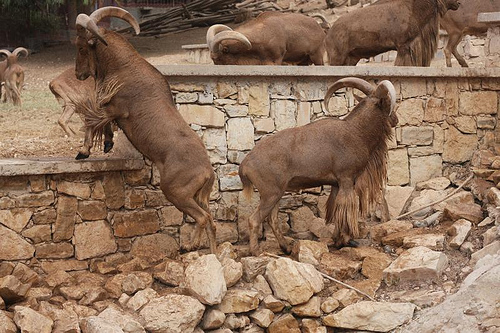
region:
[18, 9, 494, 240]
numerous rams in enclousure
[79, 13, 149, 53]
rams have brown horns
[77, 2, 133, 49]
brown horns are curved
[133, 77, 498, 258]
stone wall in enclosure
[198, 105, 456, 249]
stone wall is light brown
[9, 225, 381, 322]
stones piled on ground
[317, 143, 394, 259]
rams have long drooping manes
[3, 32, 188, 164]
brown dirt behind wall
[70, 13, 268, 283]
ram is climbing wall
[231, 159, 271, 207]
ram has short brown tail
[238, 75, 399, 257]
the animal on the rocks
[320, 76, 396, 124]
the horns on the animal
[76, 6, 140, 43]
the horns on the animal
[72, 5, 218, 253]
the animal climbing on the rock wall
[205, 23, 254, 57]
the horns on the animal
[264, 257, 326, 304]
the large rock on the ground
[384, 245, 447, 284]
the large rock on the ground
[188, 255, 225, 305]
the large rock on the ground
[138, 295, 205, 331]
the large rock on the ground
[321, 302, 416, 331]
the large rock on the ground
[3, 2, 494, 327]
Goats in a rocky surroundings.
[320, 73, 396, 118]
Goat with long horns.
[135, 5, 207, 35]
Background with stacked stones panels.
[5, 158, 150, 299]
Stone fenced wall.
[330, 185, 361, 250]
Goat's front leg is covered with long hair.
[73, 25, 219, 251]
Goat's fur is brown.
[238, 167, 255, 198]
Goat has short tail.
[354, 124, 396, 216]
Long hair hanging on the goat's chest.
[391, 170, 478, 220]
Long stick of wood among the stones.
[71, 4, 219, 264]
Goat climbing up the fence.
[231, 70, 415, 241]
brown mountain cow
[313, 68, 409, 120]
long horns on mountain goat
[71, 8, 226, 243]
brown mountain goat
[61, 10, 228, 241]
long horned mountain goat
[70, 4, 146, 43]
long horns on head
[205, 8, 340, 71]
long horn on mountain goat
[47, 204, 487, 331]
rocks piled on ground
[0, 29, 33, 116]
horns on mountain goat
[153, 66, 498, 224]
concrete wall in front of goats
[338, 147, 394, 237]
long hair on mountain goat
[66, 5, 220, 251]
a ram jumping on wall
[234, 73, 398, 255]
a ram walking on rocks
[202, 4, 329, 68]
a large ram grazing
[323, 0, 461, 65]
a large ram standing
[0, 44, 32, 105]
a large ram walking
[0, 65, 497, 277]
a large stone wall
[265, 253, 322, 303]
a large loose stone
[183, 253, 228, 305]
a large loose stone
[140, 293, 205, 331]
a large loose stone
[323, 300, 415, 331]
a large loose stone